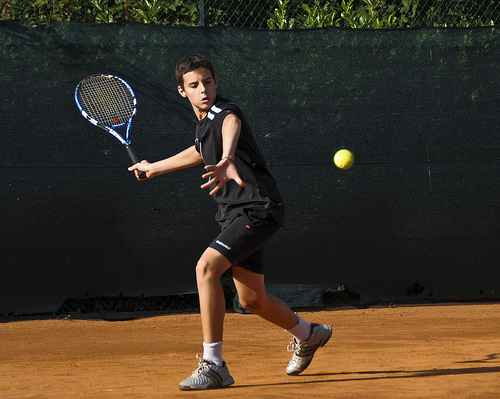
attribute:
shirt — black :
[139, 103, 293, 215]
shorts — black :
[190, 180, 295, 274]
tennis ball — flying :
[327, 138, 368, 178]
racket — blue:
[70, 62, 159, 155]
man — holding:
[103, 46, 407, 352]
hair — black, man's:
[160, 55, 224, 90]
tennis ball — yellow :
[324, 140, 367, 182]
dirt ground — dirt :
[16, 330, 162, 388]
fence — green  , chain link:
[206, 2, 495, 30]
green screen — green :
[297, 51, 497, 132]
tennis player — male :
[128, 50, 334, 390]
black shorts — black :
[179, 210, 296, 286]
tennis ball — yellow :
[330, 144, 359, 176]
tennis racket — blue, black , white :
[68, 71, 151, 177]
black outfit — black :
[187, 98, 294, 278]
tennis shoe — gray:
[180, 352, 237, 396]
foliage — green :
[4, 0, 490, 23]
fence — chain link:
[22, 0, 496, 310]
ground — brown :
[6, 314, 481, 393]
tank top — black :
[183, 100, 283, 210]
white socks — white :
[201, 343, 225, 359]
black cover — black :
[1, 32, 495, 316]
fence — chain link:
[0, 19, 496, 314]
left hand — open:
[198, 153, 244, 193]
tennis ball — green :
[329, 147, 359, 166]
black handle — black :
[116, 137, 146, 185]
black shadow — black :
[225, 350, 497, 388]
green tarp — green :
[0, 30, 493, 315]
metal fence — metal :
[3, 2, 493, 313]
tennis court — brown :
[3, 319, 498, 392]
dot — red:
[108, 112, 121, 126]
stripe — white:
[202, 107, 214, 120]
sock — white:
[197, 334, 232, 365]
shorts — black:
[198, 191, 293, 273]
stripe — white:
[205, 106, 223, 125]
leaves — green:
[2, 1, 499, 156]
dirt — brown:
[2, 281, 495, 394]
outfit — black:
[181, 88, 289, 281]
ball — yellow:
[326, 144, 363, 175]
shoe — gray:
[178, 342, 239, 396]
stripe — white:
[198, 96, 230, 116]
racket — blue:
[73, 64, 147, 183]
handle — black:
[118, 134, 151, 191]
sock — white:
[191, 332, 231, 365]